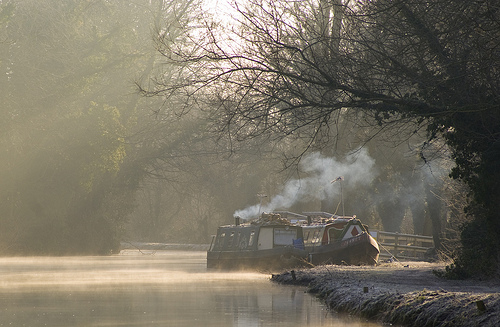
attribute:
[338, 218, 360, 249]
square — white, red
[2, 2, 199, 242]
leaves — green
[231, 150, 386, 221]
smoke — rising, gray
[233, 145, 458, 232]
smoke — white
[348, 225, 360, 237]
diamond — red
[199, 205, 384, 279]
boats — old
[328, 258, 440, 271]
light — shining